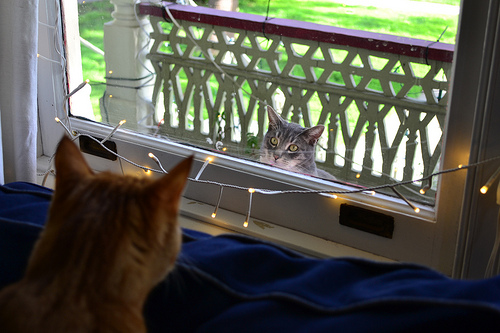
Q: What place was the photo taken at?
A: It was taken at the patio.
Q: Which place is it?
A: It is a patio.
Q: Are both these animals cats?
A: Yes, all the animals are cats.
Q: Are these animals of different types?
A: No, all the animals are cats.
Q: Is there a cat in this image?
A: Yes, there is a cat.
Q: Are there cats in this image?
A: Yes, there is a cat.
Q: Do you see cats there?
A: Yes, there is a cat.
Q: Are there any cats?
A: Yes, there is a cat.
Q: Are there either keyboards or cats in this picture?
A: Yes, there is a cat.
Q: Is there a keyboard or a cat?
A: Yes, there is a cat.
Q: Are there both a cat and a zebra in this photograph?
A: No, there is a cat but no zebras.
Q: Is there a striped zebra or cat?
A: Yes, there is a striped cat.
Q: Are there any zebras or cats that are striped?
A: Yes, the cat is striped.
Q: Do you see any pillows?
A: No, there are no pillows.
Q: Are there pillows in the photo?
A: No, there are no pillows.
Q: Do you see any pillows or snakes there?
A: No, there are no pillows or snakes.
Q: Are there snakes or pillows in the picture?
A: No, there are no pillows or snakes.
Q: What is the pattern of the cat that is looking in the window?
A: The cat is striped.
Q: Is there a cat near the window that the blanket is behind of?
A: Yes, there is a cat near the window.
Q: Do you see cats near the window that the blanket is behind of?
A: Yes, there is a cat near the window.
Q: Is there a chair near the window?
A: No, there is a cat near the window.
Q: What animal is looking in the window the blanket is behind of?
A: The cat is looking in the window.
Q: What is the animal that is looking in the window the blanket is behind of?
A: The animal is a cat.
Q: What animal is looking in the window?
A: The animal is a cat.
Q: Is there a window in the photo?
A: Yes, there is a window.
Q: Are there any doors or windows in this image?
A: Yes, there is a window.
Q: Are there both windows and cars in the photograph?
A: No, there is a window but no cars.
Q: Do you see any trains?
A: No, there are no trains.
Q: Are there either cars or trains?
A: No, there are no trains or cars.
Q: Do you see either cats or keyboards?
A: Yes, there is a cat.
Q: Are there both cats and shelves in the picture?
A: No, there is a cat but no shelves.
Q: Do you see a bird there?
A: No, there are no birds.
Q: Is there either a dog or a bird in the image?
A: No, there are no birds or dogs.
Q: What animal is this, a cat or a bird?
A: This is a cat.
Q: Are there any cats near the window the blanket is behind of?
A: Yes, there is a cat near the window.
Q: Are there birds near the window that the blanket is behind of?
A: No, there is a cat near the window.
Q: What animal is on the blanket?
A: The cat is on the blanket.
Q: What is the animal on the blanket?
A: The animal is a cat.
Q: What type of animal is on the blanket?
A: The animal is a cat.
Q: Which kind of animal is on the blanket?
A: The animal is a cat.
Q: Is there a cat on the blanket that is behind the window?
A: Yes, there is a cat on the blanket.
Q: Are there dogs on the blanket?
A: No, there is a cat on the blanket.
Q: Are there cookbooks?
A: No, there are no cookbooks.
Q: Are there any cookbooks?
A: No, there are no cookbooks.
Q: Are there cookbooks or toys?
A: No, there are no cookbooks or toys.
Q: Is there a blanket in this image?
A: Yes, there is a blanket.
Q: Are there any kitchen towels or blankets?
A: Yes, there is a blanket.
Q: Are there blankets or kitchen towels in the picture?
A: Yes, there is a blanket.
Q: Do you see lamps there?
A: No, there are no lamps.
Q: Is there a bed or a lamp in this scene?
A: No, there are no lamps or beds.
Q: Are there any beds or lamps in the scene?
A: No, there are no lamps or beds.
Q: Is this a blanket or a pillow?
A: This is a blanket.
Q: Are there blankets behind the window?
A: Yes, there is a blanket behind the window.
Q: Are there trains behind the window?
A: No, there is a blanket behind the window.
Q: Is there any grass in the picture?
A: Yes, there is grass.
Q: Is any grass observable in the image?
A: Yes, there is grass.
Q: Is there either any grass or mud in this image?
A: Yes, there is grass.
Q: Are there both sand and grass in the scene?
A: No, there is grass but no sand.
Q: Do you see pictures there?
A: No, there are no pictures.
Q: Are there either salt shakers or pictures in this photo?
A: No, there are no pictures or salt shakers.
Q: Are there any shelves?
A: No, there are no shelves.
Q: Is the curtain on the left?
A: Yes, the curtain is on the left of the image.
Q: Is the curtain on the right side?
A: No, the curtain is on the left of the image.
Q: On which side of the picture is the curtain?
A: The curtain is on the left of the image.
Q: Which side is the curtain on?
A: The curtain is on the left of the image.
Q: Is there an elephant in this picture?
A: No, there are no elephants.